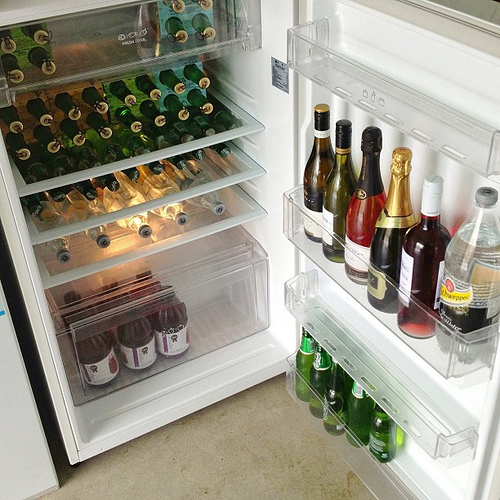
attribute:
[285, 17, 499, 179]
door shelf — empty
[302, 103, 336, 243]
bottle — brown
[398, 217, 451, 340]
wine — alcoholic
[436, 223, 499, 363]
tonic water — colorless, clear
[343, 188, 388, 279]
wine — pink, blush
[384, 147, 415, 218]
foil — gold, yellow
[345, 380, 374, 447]
bottle — green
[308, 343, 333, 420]
bottle — green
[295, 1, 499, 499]
door — open, full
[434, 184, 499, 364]
bottle — clear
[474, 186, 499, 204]
cap — grey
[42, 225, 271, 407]
drawer — filled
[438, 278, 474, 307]
label — yellow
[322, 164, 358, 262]
wine — white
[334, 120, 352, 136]
screw cap — black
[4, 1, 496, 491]
refrigerator — clean, white, full